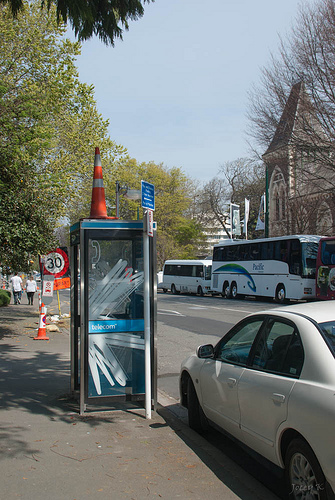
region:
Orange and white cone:
[55, 137, 114, 230]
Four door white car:
[188, 330, 333, 430]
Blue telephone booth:
[55, 216, 169, 429]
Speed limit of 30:
[36, 247, 74, 281]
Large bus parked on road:
[206, 233, 330, 312]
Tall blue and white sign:
[134, 167, 162, 215]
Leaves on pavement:
[89, 436, 172, 497]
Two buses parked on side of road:
[159, 246, 316, 304]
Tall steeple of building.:
[249, 96, 328, 232]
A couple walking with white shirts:
[11, 262, 42, 306]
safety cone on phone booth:
[79, 145, 121, 218]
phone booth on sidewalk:
[70, 222, 157, 412]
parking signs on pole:
[139, 180, 155, 423]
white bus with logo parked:
[210, 234, 318, 299]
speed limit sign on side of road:
[39, 247, 71, 317]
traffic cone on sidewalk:
[33, 301, 49, 339]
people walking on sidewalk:
[10, 272, 37, 303]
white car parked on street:
[179, 296, 334, 498]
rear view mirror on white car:
[194, 344, 216, 359]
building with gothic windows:
[265, 145, 332, 235]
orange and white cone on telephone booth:
[83, 145, 116, 219]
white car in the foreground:
[180, 300, 334, 492]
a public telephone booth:
[69, 218, 158, 409]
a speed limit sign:
[37, 246, 70, 276]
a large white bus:
[212, 235, 319, 300]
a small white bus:
[162, 257, 212, 294]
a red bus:
[316, 236, 334, 298]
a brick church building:
[260, 122, 333, 239]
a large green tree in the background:
[0, 75, 104, 264]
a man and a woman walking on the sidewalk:
[9, 271, 38, 306]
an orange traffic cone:
[81, 144, 122, 229]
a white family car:
[178, 300, 333, 491]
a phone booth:
[67, 221, 159, 429]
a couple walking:
[6, 264, 44, 308]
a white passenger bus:
[206, 234, 327, 301]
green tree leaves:
[1, 33, 99, 210]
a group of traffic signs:
[37, 250, 74, 322]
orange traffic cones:
[34, 289, 50, 349]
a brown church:
[263, 77, 333, 240]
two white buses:
[160, 237, 321, 306]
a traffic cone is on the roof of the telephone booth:
[83, 143, 122, 220]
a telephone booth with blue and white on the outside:
[70, 222, 158, 410]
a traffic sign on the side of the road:
[37, 245, 72, 320]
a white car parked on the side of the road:
[163, 296, 333, 495]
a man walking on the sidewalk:
[7, 270, 25, 303]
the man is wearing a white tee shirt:
[9, 275, 23, 291]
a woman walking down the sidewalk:
[23, 273, 37, 306]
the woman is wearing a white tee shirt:
[24, 279, 38, 292]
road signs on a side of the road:
[141, 179, 160, 420]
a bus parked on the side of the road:
[209, 233, 316, 302]